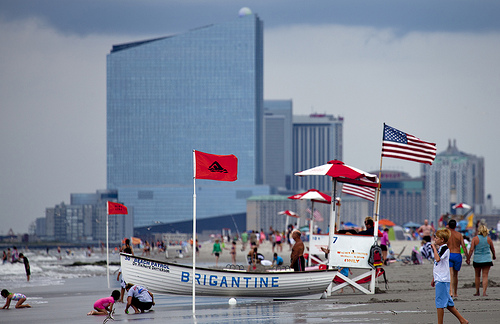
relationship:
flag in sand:
[192, 148, 238, 317] [1, 239, 495, 322]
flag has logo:
[192, 148, 238, 317] [206, 160, 229, 174]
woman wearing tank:
[465, 221, 496, 294] [472, 233, 493, 264]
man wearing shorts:
[445, 220, 468, 300] [448, 253, 462, 270]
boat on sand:
[119, 250, 338, 300] [1, 239, 495, 322]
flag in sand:
[374, 121, 438, 247] [1, 239, 495, 322]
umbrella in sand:
[293, 159, 377, 295] [1, 239, 495, 322]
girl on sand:
[84, 288, 120, 317] [1, 239, 495, 322]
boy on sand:
[430, 229, 470, 324] [1, 239, 495, 322]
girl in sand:
[1, 289, 32, 309] [1, 239, 495, 322]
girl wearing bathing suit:
[1, 289, 32, 309] [10, 293, 28, 300]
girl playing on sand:
[1, 289, 32, 309] [1, 239, 495, 322]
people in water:
[1, 210, 500, 324] [3, 247, 123, 288]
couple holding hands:
[443, 218, 497, 300] [464, 256, 472, 265]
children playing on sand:
[1, 280, 158, 318] [1, 239, 495, 322]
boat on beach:
[119, 250, 338, 300] [0, 237, 499, 324]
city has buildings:
[1, 0, 500, 248] [30, 7, 498, 234]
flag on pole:
[192, 148, 238, 317] [191, 150, 197, 324]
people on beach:
[1, 210, 499, 323] [1, 239, 499, 323]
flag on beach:
[374, 121, 438, 247] [1, 239, 499, 323]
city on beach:
[1, 0, 500, 248] [1, 239, 499, 323]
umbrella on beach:
[293, 159, 377, 295] [1, 239, 499, 323]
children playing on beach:
[1, 280, 158, 318] [1, 239, 499, 323]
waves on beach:
[1, 252, 121, 277] [1, 239, 499, 323]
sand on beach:
[1, 239, 495, 322] [1, 239, 499, 323]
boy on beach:
[430, 229, 470, 324] [1, 239, 499, 323]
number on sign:
[333, 235, 339, 244] [329, 234, 373, 270]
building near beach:
[105, 6, 265, 231] [1, 239, 499, 323]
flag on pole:
[374, 121, 438, 247] [374, 121, 386, 238]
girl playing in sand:
[84, 288, 120, 317] [1, 239, 495, 322]